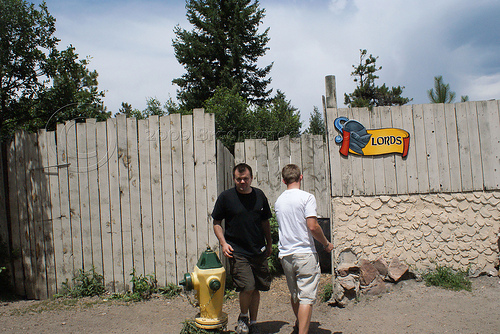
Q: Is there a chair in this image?
A: No, there are no chairs.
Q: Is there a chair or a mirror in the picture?
A: No, there are no chairs or mirrors.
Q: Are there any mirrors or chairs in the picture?
A: No, there are no chairs or mirrors.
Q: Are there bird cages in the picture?
A: No, there are no bird cages.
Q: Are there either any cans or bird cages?
A: No, there are no bird cages or cans.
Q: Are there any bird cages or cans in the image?
A: No, there are no bird cages or cans.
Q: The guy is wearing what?
A: The guy is wearing shorts.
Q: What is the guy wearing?
A: The guy is wearing shorts.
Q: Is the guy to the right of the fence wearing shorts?
A: Yes, the guy is wearing shorts.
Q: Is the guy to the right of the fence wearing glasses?
A: No, the guy is wearing shorts.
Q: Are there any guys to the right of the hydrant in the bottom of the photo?
A: Yes, there is a guy to the right of the hydrant.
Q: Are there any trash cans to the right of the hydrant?
A: No, there is a guy to the right of the hydrant.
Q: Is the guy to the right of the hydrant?
A: Yes, the guy is to the right of the hydrant.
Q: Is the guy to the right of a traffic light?
A: No, the guy is to the right of the hydrant.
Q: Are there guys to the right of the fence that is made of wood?
A: Yes, there is a guy to the right of the fence.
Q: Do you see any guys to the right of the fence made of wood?
A: Yes, there is a guy to the right of the fence.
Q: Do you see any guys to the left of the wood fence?
A: No, the guy is to the right of the fence.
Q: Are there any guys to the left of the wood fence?
A: No, the guy is to the right of the fence.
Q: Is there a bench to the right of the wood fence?
A: No, there is a guy to the right of the fence.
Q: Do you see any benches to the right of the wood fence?
A: No, there is a guy to the right of the fence.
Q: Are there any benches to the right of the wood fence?
A: No, there is a guy to the right of the fence.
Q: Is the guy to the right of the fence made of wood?
A: Yes, the guy is to the right of the fence.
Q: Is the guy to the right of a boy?
A: No, the guy is to the right of the fence.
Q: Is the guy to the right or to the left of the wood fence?
A: The guy is to the right of the fence.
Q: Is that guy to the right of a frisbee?
A: No, the guy is to the right of the fence.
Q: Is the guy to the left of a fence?
A: No, the guy is to the right of a fence.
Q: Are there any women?
A: No, there are no women.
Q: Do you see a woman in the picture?
A: No, there are no women.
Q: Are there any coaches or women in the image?
A: No, there are no women or coaches.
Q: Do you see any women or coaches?
A: No, there are no women or coaches.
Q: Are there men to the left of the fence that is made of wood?
A: No, the men are to the right of the fence.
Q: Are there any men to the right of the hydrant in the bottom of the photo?
A: Yes, there are men to the right of the fire hydrant.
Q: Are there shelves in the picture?
A: No, there are no shelves.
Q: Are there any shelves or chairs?
A: No, there are no shelves or chairs.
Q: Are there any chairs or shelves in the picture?
A: No, there are no shelves or chairs.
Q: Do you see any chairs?
A: No, there are no chairs.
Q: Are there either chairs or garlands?
A: No, there are no chairs or garlands.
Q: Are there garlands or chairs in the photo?
A: No, there are no chairs or garlands.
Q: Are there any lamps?
A: No, there are no lamps.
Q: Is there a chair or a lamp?
A: No, there are no lamps or chairs.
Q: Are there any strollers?
A: No, there are no strollers.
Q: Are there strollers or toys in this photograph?
A: No, there are no strollers or toys.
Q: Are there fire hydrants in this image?
A: Yes, there is a fire hydrant.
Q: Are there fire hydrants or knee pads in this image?
A: Yes, there is a fire hydrant.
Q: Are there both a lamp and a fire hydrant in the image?
A: No, there is a fire hydrant but no lamps.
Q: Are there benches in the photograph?
A: No, there are no benches.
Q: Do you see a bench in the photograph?
A: No, there are no benches.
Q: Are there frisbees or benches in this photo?
A: No, there are no benches or frisbees.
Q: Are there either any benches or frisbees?
A: No, there are no benches or frisbees.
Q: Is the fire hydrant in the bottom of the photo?
A: Yes, the fire hydrant is in the bottom of the image.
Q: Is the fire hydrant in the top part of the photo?
A: No, the fire hydrant is in the bottom of the image.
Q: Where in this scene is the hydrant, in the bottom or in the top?
A: The hydrant is in the bottom of the image.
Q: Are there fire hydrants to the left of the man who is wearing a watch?
A: Yes, there is a fire hydrant to the left of the man.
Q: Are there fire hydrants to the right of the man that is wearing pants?
A: No, the fire hydrant is to the left of the man.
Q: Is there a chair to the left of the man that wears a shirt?
A: No, there is a fire hydrant to the left of the man.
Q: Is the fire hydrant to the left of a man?
A: Yes, the fire hydrant is to the left of a man.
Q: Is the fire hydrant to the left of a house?
A: No, the fire hydrant is to the left of a man.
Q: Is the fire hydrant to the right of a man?
A: No, the fire hydrant is to the left of a man.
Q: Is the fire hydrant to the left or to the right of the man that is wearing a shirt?
A: The fire hydrant is to the left of the man.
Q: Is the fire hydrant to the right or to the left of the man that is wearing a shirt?
A: The fire hydrant is to the left of the man.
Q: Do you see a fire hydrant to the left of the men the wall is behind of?
A: Yes, there is a fire hydrant to the left of the men.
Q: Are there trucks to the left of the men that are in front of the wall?
A: No, there is a fire hydrant to the left of the men.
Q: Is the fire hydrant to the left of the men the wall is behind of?
A: Yes, the fire hydrant is to the left of the men.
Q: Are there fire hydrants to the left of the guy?
A: Yes, there is a fire hydrant to the left of the guy.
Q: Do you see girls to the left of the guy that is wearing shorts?
A: No, there is a fire hydrant to the left of the guy.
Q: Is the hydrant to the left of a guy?
A: Yes, the hydrant is to the left of a guy.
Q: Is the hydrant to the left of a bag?
A: No, the hydrant is to the left of a guy.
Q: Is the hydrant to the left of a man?
A: Yes, the hydrant is to the left of a man.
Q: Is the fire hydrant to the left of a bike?
A: No, the fire hydrant is to the left of a man.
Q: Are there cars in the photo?
A: No, there are no cars.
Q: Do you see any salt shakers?
A: No, there are no salt shakers.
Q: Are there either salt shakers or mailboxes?
A: No, there are no salt shakers or mailboxes.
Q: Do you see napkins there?
A: No, there are no napkins.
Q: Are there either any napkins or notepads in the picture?
A: No, there are no napkins or notepads.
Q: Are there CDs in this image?
A: No, there are no cds.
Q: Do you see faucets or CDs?
A: No, there are no CDs or faucets.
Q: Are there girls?
A: No, there are no girls.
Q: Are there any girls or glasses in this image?
A: No, there are no girls or glasses.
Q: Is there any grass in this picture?
A: Yes, there is grass.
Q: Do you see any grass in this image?
A: Yes, there is grass.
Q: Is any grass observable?
A: Yes, there is grass.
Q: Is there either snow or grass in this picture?
A: Yes, there is grass.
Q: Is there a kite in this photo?
A: No, there are no kites.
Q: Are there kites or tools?
A: No, there are no kites or tools.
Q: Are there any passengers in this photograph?
A: No, there are no passengers.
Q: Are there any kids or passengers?
A: No, there are no passengers or kids.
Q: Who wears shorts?
A: The man wears shorts.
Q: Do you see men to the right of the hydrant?
A: Yes, there is a man to the right of the hydrant.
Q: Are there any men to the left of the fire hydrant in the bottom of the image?
A: No, the man is to the right of the hydrant.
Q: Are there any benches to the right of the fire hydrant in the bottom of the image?
A: No, there is a man to the right of the fire hydrant.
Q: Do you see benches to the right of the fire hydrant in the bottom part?
A: No, there is a man to the right of the fire hydrant.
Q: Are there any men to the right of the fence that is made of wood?
A: Yes, there is a man to the right of the fence.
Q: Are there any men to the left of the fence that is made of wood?
A: No, the man is to the right of the fence.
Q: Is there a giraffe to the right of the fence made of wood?
A: No, there is a man to the right of the fence.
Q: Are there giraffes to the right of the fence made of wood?
A: No, there is a man to the right of the fence.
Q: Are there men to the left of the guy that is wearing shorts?
A: Yes, there is a man to the left of the guy.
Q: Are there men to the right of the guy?
A: No, the man is to the left of the guy.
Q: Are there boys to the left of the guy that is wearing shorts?
A: No, there is a man to the left of the guy.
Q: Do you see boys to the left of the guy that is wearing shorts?
A: No, there is a man to the left of the guy.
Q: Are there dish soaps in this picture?
A: No, there are no dish soaps.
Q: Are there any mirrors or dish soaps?
A: No, there are no dish soaps or mirrors.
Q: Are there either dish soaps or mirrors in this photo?
A: No, there are no dish soaps or mirrors.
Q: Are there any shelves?
A: No, there are no shelves.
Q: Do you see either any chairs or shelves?
A: No, there are no shelves or chairs.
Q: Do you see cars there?
A: No, there are no cars.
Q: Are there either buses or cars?
A: No, there are no cars or buses.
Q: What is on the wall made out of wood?
A: The sign is on the wall.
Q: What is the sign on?
A: The sign is on the wall.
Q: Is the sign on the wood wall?
A: Yes, the sign is on the wall.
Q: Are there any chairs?
A: No, there are no chairs.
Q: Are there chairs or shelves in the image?
A: No, there are no chairs or shelves.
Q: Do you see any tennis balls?
A: No, there are no tennis balls.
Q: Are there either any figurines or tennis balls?
A: No, there are no tennis balls or figurines.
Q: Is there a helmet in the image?
A: No, there are no helmets.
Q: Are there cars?
A: No, there are no cars.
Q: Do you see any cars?
A: No, there are no cars.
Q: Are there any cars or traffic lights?
A: No, there are no cars or traffic lights.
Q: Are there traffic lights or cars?
A: No, there are no cars or traffic lights.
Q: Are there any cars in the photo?
A: No, there are no cars.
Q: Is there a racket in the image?
A: No, there are no rackets.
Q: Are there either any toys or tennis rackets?
A: No, there are no tennis rackets or toys.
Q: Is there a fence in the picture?
A: Yes, there is a fence.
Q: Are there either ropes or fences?
A: Yes, there is a fence.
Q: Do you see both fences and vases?
A: No, there is a fence but no vases.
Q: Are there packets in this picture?
A: No, there are no packets.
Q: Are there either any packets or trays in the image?
A: No, there are no packets or trays.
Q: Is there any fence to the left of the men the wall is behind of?
A: Yes, there is a fence to the left of the men.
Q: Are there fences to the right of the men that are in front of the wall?
A: No, the fence is to the left of the men.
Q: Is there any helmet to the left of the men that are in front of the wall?
A: No, there is a fence to the left of the men.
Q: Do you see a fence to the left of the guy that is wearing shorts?
A: Yes, there is a fence to the left of the guy.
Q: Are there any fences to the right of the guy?
A: No, the fence is to the left of the guy.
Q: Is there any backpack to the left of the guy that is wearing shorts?
A: No, there is a fence to the left of the guy.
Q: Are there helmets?
A: No, there are no helmets.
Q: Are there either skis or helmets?
A: No, there are no helmets or skis.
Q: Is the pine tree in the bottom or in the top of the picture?
A: The pine tree is in the top of the image.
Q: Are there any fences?
A: Yes, there is a fence.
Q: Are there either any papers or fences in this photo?
A: Yes, there is a fence.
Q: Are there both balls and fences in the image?
A: No, there is a fence but no balls.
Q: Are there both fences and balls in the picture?
A: No, there is a fence but no balls.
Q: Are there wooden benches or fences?
A: Yes, there is a wood fence.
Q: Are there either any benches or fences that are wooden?
A: Yes, the fence is wooden.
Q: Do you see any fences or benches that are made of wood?
A: Yes, the fence is made of wood.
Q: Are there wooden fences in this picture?
A: Yes, there is a wood fence.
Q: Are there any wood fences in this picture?
A: Yes, there is a wood fence.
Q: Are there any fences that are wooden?
A: Yes, there is a fence that is wooden.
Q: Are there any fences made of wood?
A: Yes, there is a fence that is made of wood.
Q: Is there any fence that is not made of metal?
A: Yes, there is a fence that is made of wood.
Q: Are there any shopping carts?
A: No, there are no shopping carts.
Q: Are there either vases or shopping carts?
A: No, there are no shopping carts or vases.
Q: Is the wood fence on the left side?
A: Yes, the fence is on the left of the image.